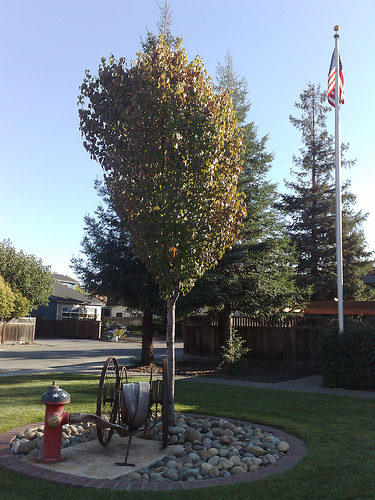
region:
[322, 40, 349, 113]
Red, white and blue flag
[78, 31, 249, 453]
A small tree with green leaves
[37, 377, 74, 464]
Red, yellow and black fire hydrant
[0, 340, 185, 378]
Shadows on the pavement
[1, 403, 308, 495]
Many big rocks in a circle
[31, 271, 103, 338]
A house in the background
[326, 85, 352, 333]
A post holding up a flag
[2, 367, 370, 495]
A lawn of green grass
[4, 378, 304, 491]
Fire hydrant in a circle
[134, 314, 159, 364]
A brown tree trunk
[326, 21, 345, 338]
american flag on a tall pole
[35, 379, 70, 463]
red fire hydrant on the ground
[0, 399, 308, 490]
large boulders in a circle around a tree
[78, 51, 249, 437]
medium size tree growing in a circle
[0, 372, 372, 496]
low cut green grass on the ground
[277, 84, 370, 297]
pine tree in the background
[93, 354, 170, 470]
item for winding up a hose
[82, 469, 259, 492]
brick pavers on the ground in a circle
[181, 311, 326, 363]
wood fence in the background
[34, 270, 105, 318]
blue hosue with a gray roof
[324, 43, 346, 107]
an american flag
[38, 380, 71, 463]
a tall red fire hydrant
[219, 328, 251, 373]
a small green tree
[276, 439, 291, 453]
a large rock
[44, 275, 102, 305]
the roof of a home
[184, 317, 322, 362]
a long wooden fence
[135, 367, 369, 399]
a long concrete sidewalk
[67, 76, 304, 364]
a tall green tree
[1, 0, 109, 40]
part of a blue sky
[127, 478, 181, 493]
red brick pavers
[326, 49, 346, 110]
An American flag.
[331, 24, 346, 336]
A silver flagpole.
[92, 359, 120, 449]
A dark wagon wheel.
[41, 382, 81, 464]
A red, white, and blue fire hydrant.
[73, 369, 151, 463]
A grey firehose.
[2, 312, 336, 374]
Brown wooden fences.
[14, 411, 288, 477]
Beige, white, and grey stones.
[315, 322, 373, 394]
A green bush.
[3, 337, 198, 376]
The road.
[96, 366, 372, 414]
A grey walking path.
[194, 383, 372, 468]
The grass is short and green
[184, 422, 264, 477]
The rocks around the tree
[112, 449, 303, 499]
The rim is made of bricks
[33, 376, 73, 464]
The fire hydrant is the color red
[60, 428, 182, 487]
The area is made of cement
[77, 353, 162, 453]
The fire hydrant hose in the front yard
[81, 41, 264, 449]
The tree is tall with green leaves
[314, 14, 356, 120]
The american flag on the pole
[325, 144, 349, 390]
The bottom of the pole holding the flag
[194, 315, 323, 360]
The gate is made of wood